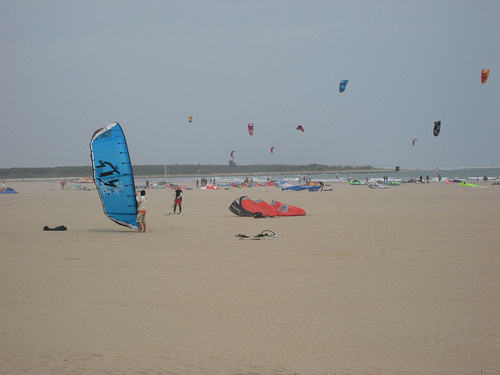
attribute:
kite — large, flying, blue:
[337, 76, 348, 93]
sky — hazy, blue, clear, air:
[1, 0, 500, 169]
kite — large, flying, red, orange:
[478, 67, 490, 84]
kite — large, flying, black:
[430, 118, 442, 137]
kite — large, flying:
[410, 136, 419, 148]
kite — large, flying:
[294, 122, 308, 132]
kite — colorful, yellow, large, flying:
[246, 121, 255, 136]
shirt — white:
[134, 195, 148, 211]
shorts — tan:
[136, 211, 147, 223]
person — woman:
[172, 185, 183, 215]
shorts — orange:
[174, 196, 182, 205]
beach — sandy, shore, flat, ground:
[3, 181, 499, 370]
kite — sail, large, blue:
[88, 120, 139, 230]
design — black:
[95, 157, 120, 189]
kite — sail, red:
[227, 192, 306, 218]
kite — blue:
[278, 183, 320, 192]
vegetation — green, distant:
[1, 164, 377, 180]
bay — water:
[103, 169, 499, 177]